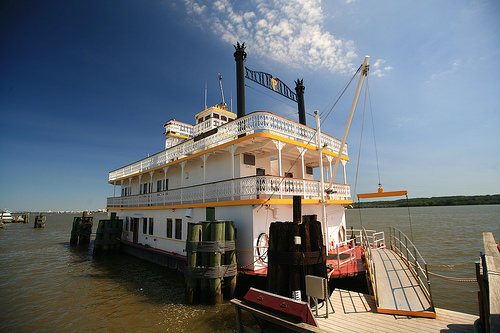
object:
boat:
[89, 49, 414, 294]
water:
[0, 280, 124, 332]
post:
[233, 38, 247, 136]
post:
[296, 77, 307, 127]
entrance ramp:
[363, 246, 435, 314]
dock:
[227, 281, 499, 332]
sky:
[1, 1, 496, 184]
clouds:
[178, 0, 400, 81]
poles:
[208, 217, 227, 304]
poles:
[94, 217, 106, 252]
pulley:
[355, 51, 409, 201]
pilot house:
[193, 104, 237, 134]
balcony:
[229, 111, 353, 161]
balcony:
[103, 175, 254, 207]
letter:
[269, 77, 280, 91]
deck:
[253, 238, 370, 276]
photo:
[0, 0, 500, 332]